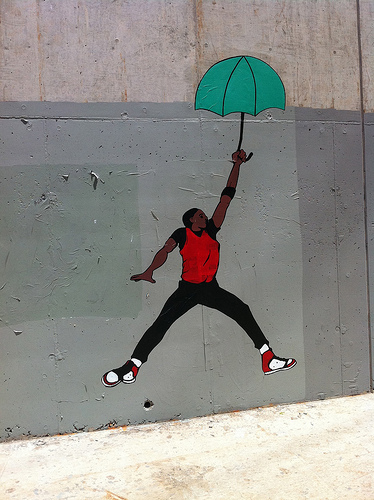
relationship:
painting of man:
[102, 54, 297, 387] [100, 148, 296, 388]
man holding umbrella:
[100, 148, 296, 388] [194, 56, 286, 163]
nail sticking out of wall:
[90, 169, 100, 182] [1, 1, 373, 444]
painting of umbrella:
[102, 54, 297, 387] [194, 56, 286, 163]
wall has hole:
[1, 1, 373, 444] [142, 399, 154, 410]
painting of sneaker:
[102, 54, 297, 387] [260, 347, 295, 375]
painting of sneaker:
[102, 54, 297, 387] [100, 359, 139, 388]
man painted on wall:
[100, 148, 296, 388] [1, 1, 373, 444]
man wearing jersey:
[100, 148, 296, 388] [179, 227, 219, 285]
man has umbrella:
[100, 148, 296, 388] [194, 56, 286, 163]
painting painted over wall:
[102, 54, 297, 387] [1, 1, 373, 444]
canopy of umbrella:
[192, 56, 286, 116] [194, 56, 286, 163]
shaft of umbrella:
[236, 111, 252, 163] [194, 56, 286, 163]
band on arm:
[220, 185, 236, 197] [210, 151, 246, 237]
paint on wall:
[1, 102, 373, 445] [1, 1, 373, 444]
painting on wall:
[102, 54, 297, 387] [1, 1, 373, 444]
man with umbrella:
[100, 148, 296, 388] [194, 56, 286, 163]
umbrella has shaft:
[194, 56, 286, 163] [236, 111, 252, 163]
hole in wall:
[142, 399, 154, 410] [1, 1, 373, 444]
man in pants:
[100, 148, 296, 388] [131, 276, 271, 363]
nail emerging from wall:
[90, 169, 100, 182] [1, 1, 373, 444]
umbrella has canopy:
[194, 56, 286, 163] [192, 56, 286, 116]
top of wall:
[0, 1, 373, 109] [1, 1, 373, 444]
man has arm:
[100, 148, 296, 388] [210, 151, 246, 237]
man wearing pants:
[100, 148, 296, 388] [131, 276, 271, 363]